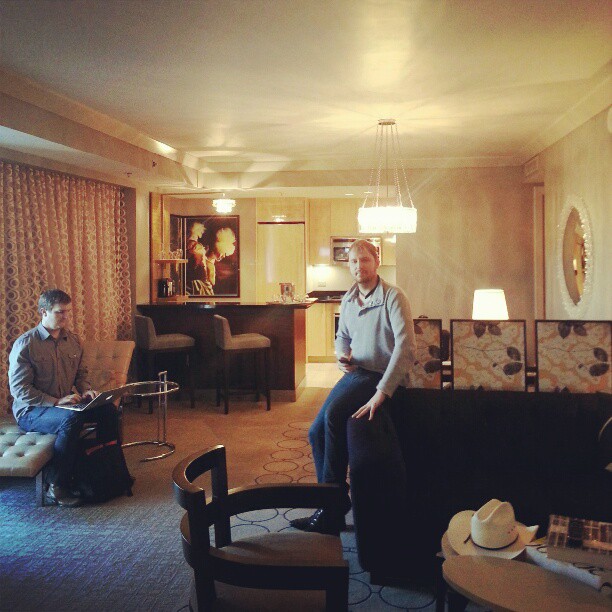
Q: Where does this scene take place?
A: In a lounge in a home.